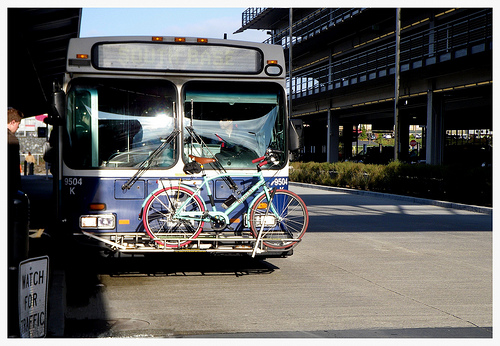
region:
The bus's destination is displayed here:
[94, 40, 266, 77]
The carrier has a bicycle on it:
[139, 147, 311, 264]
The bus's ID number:
[59, 171, 92, 209]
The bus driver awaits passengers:
[205, 112, 280, 165]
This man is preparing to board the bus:
[8, 105, 75, 247]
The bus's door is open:
[49, 77, 108, 182]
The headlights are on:
[73, 208, 142, 255]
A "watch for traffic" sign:
[15, 252, 62, 342]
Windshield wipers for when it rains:
[157, 99, 209, 175]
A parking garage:
[291, 16, 491, 193]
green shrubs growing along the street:
[287, 158, 494, 205]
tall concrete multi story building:
[239, 7, 491, 209]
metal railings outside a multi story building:
[286, 19, 493, 101]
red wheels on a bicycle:
[142, 183, 311, 252]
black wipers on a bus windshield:
[119, 123, 239, 197]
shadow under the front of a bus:
[86, 247, 291, 282]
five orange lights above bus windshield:
[72, 32, 284, 79]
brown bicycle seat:
[185, 151, 217, 167]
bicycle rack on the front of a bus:
[80, 221, 296, 261]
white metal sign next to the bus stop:
[14, 252, 52, 336]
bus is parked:
[59, 31, 312, 266]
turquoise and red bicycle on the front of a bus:
[137, 148, 310, 253]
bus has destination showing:
[98, 37, 260, 74]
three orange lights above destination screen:
[146, 34, 213, 44]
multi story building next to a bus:
[239, 8, 492, 205]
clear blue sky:
[80, 10, 300, 52]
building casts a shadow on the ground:
[284, 186, 499, 251]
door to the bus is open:
[63, 81, 102, 178]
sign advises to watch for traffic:
[12, 253, 51, 338]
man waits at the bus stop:
[7, 106, 27, 238]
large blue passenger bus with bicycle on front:
[33, 24, 433, 309]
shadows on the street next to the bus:
[307, 166, 471, 249]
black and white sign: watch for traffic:
[12, 244, 68, 324]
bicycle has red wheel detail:
[134, 179, 314, 265]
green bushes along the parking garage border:
[298, 139, 429, 223]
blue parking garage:
[232, 8, 465, 93]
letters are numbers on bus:
[59, 164, 86, 207]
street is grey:
[315, 251, 444, 306]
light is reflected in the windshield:
[98, 84, 271, 166]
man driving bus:
[203, 111, 255, 174]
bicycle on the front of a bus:
[135, 156, 314, 257]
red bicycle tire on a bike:
[142, 191, 209, 251]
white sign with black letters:
[14, 262, 52, 336]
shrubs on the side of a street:
[335, 157, 387, 196]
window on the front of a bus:
[71, 75, 178, 168]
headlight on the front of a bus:
[76, 210, 121, 231]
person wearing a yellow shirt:
[24, 147, 39, 172]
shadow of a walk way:
[358, 192, 398, 234]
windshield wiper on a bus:
[124, 126, 178, 178]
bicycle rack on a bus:
[110, 232, 288, 260]